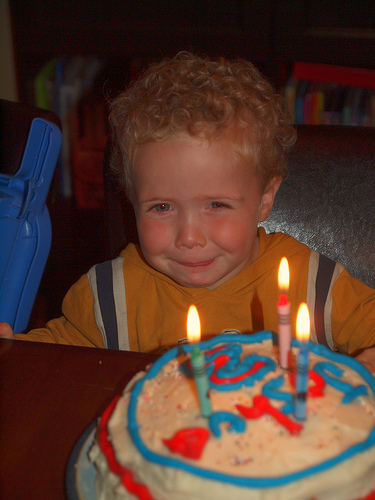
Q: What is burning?
A: Candles.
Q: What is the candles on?
A: Cake.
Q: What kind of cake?
A: Birthday.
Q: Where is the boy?
A: Behind the cake.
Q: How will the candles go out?
A: He will blow on them.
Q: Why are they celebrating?
A: Its his birthday.